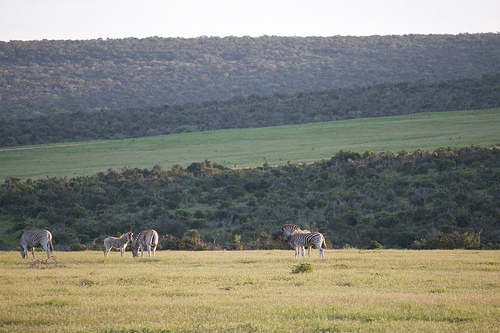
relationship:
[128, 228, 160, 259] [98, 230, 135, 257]
zebra with zebra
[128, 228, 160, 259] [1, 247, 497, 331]
zebra in grass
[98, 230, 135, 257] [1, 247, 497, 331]
zebra in grass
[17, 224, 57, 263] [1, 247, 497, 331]
zebra in grass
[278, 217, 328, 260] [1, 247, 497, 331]
zebra in grass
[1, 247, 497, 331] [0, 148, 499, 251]
grass near trees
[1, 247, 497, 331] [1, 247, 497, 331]
grass in grass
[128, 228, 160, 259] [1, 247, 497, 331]
zebra eating grass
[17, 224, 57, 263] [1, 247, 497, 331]
zebra eating grass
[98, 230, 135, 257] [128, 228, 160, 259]
zebra with zebra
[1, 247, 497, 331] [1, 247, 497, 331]
grass of grass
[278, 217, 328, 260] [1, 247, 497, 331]
zebra on grass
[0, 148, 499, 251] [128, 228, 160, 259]
trees near zebra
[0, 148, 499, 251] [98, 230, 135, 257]
trees near zebra